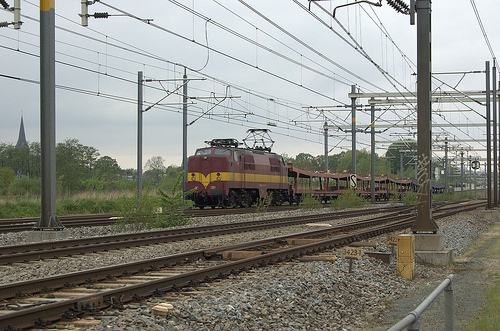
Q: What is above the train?
A: The sky.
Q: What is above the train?
A: Wires.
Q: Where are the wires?
A: Above the train.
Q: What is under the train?
A: Tracks.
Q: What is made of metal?
A: The poles.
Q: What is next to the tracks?
A: Grass.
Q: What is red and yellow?
A: Train.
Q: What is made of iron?
A: The tracks.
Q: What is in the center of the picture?
A: A train.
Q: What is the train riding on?
A: Train tracks.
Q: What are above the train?
A: Wired lines.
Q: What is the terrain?
A: A rocky flat terrain.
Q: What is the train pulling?
A: Train cars.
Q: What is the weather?
A: Grey cloudy skies.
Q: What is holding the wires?
A: Metal poles.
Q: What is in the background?
A: Green trees.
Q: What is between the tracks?
A: Gravel.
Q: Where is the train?
A: On the furthest track.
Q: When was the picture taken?
A: Daytime.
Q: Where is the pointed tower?
A: To the far left.